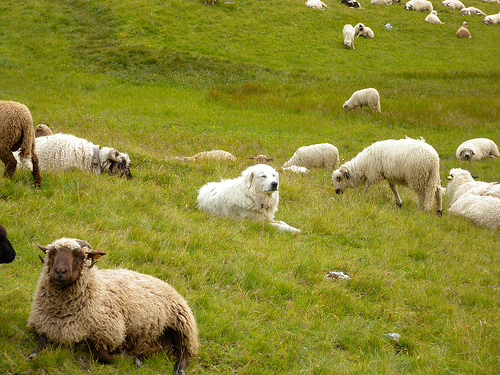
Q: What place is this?
A: It is a field.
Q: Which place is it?
A: It is a field.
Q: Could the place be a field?
A: Yes, it is a field.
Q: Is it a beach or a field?
A: It is a field.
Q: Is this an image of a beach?
A: No, the picture is showing a field.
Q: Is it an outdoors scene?
A: Yes, it is outdoors.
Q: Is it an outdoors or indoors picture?
A: It is outdoors.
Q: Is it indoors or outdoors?
A: It is outdoors.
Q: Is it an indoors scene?
A: No, it is outdoors.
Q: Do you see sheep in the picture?
A: Yes, there is a sheep.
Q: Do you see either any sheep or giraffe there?
A: Yes, there is a sheep.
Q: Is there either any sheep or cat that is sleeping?
A: Yes, the sheep is sleeping.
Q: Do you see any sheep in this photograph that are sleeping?
A: Yes, there is a sheep that is sleeping.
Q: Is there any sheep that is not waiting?
A: Yes, there is a sheep that is sleeping.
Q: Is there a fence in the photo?
A: No, there are no fences.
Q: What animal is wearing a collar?
A: The sheep is wearing a collar.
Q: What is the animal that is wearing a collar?
A: The animal is a sheep.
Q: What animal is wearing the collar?
A: The animal is a sheep.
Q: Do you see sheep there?
A: Yes, there is a sheep.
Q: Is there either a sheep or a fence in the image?
A: Yes, there is a sheep.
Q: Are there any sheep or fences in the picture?
A: Yes, there is a sheep.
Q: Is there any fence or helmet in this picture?
A: No, there are no fences or helmets.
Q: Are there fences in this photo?
A: No, there are no fences.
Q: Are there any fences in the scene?
A: No, there are no fences.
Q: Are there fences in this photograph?
A: No, there are no fences.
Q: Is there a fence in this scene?
A: No, there are no fences.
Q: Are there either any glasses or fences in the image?
A: No, there are no fences or glasses.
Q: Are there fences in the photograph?
A: No, there are no fences.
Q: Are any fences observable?
A: No, there are no fences.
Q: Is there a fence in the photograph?
A: No, there are no fences.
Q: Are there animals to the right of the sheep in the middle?
A: Yes, there is an animal to the right of the sheep.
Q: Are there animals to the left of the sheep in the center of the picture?
A: No, the animal is to the right of the sheep.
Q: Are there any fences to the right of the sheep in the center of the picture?
A: No, there is an animal to the right of the sheep.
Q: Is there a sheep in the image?
A: Yes, there is a sheep.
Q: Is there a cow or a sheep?
A: Yes, there is a sheep.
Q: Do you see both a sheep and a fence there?
A: No, there is a sheep but no fences.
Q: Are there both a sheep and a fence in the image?
A: No, there is a sheep but no fences.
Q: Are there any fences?
A: No, there are no fences.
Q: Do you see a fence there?
A: No, there are no fences.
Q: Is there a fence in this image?
A: No, there are no fences.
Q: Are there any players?
A: No, there are no players.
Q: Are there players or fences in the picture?
A: No, there are no players or fences.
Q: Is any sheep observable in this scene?
A: Yes, there is a sheep.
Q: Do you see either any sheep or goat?
A: Yes, there is a sheep.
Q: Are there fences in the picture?
A: No, there are no fences.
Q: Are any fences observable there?
A: No, there are no fences.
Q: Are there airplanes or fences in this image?
A: No, there are no fences or airplanes.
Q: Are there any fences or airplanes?
A: No, there are no fences or airplanes.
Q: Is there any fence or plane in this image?
A: No, there are no fences or airplanes.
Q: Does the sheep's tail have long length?
A: Yes, the tail is long.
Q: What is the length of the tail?
A: The tail is long.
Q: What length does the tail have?
A: The tail has long length.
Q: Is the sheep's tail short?
A: No, the tail is long.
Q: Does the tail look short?
A: No, the tail is long.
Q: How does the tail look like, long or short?
A: The tail is long.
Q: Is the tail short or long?
A: The tail is long.